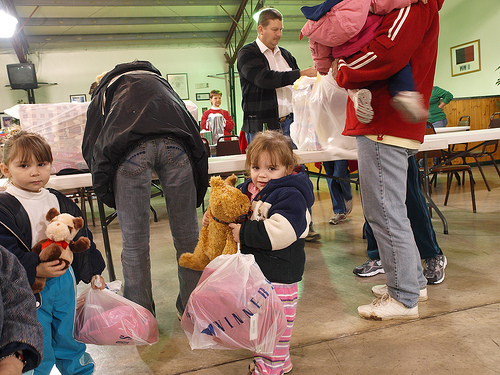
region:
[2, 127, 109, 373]
This is a baby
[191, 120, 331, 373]
This is a baby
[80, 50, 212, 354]
This is a person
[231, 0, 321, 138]
This is a person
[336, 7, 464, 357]
This is a person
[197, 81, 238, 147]
This is a person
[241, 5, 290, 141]
This is a person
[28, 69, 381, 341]
these are little girls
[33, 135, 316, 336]
the children are little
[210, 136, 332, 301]
the girl is smiling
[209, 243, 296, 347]
the bag is plastic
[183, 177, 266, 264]
the bear is brown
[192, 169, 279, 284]
this is a stuffed animal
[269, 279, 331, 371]
the girl has pink pants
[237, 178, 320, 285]
the girl has a jacket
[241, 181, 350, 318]
the jacket is white and black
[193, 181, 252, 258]
girl holding a brown teddy bear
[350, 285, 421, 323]
person wearing white shoes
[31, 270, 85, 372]
girl wearing blue pants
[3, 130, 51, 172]
girl with brown hair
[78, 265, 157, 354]
girl holding a plastic bag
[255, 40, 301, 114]
man wearing a white shirt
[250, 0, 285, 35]
man with short hair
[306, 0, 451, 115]
person holding a baby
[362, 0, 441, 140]
person wearing a red jacket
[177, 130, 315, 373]
Little girl holding a stuffed brown animal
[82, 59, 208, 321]
Person wearing black windbreaker coat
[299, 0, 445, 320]
Person holding small child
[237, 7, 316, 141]
Man looking and working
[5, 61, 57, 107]
Television mounted and extended from wall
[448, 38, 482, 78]
Wall picture in gold frame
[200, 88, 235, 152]
Woman wearing red sweater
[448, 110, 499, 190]
Two brown metal chairs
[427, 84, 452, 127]
Person wearing green long sleeve shirt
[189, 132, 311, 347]
girl holding a teddybear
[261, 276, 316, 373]
girl wearing pink pants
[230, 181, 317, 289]
girl wearing a blue jacket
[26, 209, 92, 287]
stuffed animal held by girl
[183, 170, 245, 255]
stuffed animal held by girl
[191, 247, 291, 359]
white bag held by girl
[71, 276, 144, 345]
white bag held by girl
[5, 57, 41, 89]
old TV on stand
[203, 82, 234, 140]
boy wearing white and red shirt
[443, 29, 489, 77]
painting on wall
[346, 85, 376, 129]
white shoe worn by child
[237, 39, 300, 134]
black sweater man is wearing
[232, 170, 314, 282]
black and white coat little girl is wearing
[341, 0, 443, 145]
red and white jacket man is wearing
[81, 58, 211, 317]
woman bending over the table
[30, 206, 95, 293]
brown and white teddy bear little girl is holding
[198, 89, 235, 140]
woman at the back of the room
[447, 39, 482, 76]
picture hanging on the wall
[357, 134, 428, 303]
gray pants man is wearing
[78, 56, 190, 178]
a view of jacket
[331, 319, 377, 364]
a view of lines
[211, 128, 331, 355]
a cute baby holding doll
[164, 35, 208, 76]
a view of wall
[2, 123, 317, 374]
Two girls holding stuffed animals.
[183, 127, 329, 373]
A girl in striped pants holding a stuffed animal.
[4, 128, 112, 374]
A girl in blue pants holding a stuffed animal.